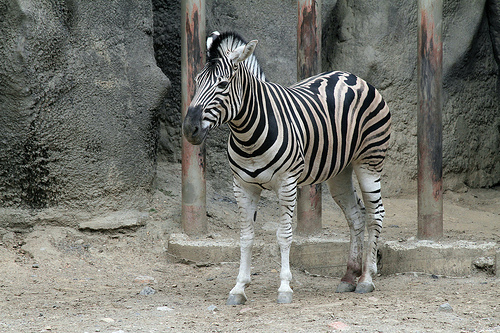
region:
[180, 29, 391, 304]
Zebra standing in front of bars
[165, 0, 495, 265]
Metal bars behind zebra.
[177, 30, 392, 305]
Young black and white striped zebra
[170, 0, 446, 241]
Three Rusted bars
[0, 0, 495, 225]
Gray stone wall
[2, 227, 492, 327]
gravelly dirt floor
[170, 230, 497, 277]
gray Concrete base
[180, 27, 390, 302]
Zebra is standing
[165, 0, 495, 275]
Poles in concrete base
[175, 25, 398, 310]
Young zebra is standing on dirt floor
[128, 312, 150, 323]
Small patch of dirt on the ground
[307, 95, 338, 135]
Black and white striped skin of zebra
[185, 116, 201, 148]
Black nose of zebra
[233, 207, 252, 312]
Right front foot of the zebra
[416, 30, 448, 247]
Wooden pillar behind the zebra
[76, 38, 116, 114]
Enormous rocks behind the pillars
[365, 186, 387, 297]
Back left foot of zebra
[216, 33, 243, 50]
Black and white hair of zebra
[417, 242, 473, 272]
Gray stone underneath the pillars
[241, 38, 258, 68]
Left ear of the zebra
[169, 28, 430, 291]
This is a zebra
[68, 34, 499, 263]
This is in a zoo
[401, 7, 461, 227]
These are posts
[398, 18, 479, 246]
The posts are made of metal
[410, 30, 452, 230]
Part of the post is black and red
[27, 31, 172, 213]
The wall in the background is stone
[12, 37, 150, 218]
This wall is gray in color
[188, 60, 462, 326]
The zebra is white and black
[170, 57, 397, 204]
The zebra is striped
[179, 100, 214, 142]
The zebras snout is black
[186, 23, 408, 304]
A small zebra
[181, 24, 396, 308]
A zebra that is standing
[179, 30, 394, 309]
A zebra with black and white stripes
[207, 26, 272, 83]
The mane of the zebra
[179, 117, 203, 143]
The black nose of the zebra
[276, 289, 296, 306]
The left front hoof of the zebra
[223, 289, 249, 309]
The right front hoof of the zebra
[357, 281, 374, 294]
The back left hoof of the zebra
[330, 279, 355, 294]
The back right hoof of the zebra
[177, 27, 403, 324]
The zoo in the zoo habitat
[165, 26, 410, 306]
the zebra on the ground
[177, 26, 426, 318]
the zebra is standing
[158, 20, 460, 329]
the zebra is striped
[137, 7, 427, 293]
the stripes are black and white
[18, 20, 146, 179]
zebra beside the rocks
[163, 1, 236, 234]
pole behind the zebra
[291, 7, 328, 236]
pole behind the zebra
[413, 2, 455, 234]
pole behind the zebra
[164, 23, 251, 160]
the head of the zebra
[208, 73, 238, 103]
eye of the zebra